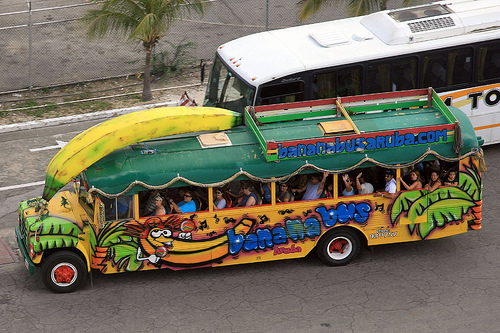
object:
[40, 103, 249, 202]
banana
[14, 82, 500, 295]
bus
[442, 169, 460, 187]
people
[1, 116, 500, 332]
road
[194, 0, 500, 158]
bus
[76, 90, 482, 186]
roof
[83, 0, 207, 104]
palm tree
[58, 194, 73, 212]
lizard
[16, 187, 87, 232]
hood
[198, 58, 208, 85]
mirror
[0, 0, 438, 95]
fence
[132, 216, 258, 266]
banana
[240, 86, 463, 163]
cargo hold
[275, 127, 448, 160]
website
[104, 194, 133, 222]
driver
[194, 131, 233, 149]
hatch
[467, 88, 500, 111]
letters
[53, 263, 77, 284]
hubcap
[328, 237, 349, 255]
hubcap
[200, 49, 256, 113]
windshield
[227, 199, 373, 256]
letters